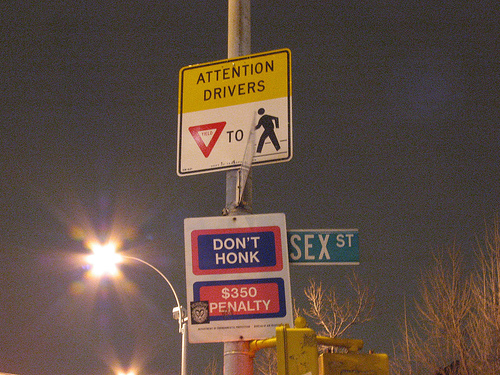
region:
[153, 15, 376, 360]
Signs on the pole.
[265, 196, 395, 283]
Green and white sign.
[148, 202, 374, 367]
Blue red and white sign.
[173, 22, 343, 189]
Yellow sign with black letters.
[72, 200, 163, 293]
Light in the sky.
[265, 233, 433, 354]
Branches in the sky.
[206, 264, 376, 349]
Dollar amount of the penalty.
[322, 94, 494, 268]
clouds in the sky.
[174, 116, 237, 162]
Yield sign on the sign.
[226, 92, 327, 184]
Person on the sign.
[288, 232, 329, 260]
the word SEX on the sign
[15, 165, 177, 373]
the light illuminating in the sky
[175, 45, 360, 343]
the signs on the pole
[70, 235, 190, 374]
the bright street light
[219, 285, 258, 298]
the $350 on the sign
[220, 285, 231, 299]
the $ on the sign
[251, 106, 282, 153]
the black walking figure on the sign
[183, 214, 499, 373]
the bare trees in the back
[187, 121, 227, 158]
the yield sign on the sign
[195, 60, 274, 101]
the words ATTENTION DRIVERS on the sign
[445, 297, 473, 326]
part of a branch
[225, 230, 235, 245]
part of a post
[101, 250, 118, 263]
part of a light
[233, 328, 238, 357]
edge of a pole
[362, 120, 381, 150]
part of the cloud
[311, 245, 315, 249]
part of a sign post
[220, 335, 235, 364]
edge of a pole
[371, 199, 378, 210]
part of the cloud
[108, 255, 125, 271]
part of a light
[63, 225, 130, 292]
The lamp to the street light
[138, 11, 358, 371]
the pole has three signs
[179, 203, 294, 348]
The sign has the colors red, white, and blue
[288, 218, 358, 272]
The sing says "sex st"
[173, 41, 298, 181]
The sign is giving directions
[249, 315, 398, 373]
The part of the sign is yellow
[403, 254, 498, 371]
The trees are brown with no leaves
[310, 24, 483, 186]
The sky is dark and gray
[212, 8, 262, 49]
The pole is the color gray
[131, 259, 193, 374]
The pole is the color white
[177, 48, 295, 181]
a caution sign is in a pole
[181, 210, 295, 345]
a blue and red sign is on the pole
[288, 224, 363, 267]
a green and white sign is on the pole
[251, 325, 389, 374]
pedestrian crosswalk signals are on the pole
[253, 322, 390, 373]
the pedestrian signals are yellow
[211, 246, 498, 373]
the trees are bare of leaves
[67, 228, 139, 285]
a street light is over the road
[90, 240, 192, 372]
the street lamp is on a steel pole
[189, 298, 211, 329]
a gold badge is on the sign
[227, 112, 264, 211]
a directional street sign is on the pole